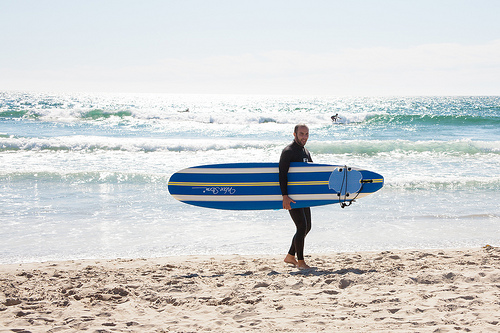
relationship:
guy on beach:
[278, 123, 320, 272] [0, 248, 484, 331]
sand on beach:
[0, 243, 500, 331] [0, 92, 499, 332]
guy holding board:
[278, 123, 320, 272] [165, 162, 384, 209]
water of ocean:
[23, 100, 130, 257] [73, 32, 490, 326]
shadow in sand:
[290, 267, 366, 276] [363, 258, 440, 285]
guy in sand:
[278, 123, 320, 272] [0, 243, 500, 331]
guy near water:
[278, 123, 320, 272] [3, 88, 498, 199]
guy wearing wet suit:
[278, 123, 320, 272] [278, 141, 313, 261]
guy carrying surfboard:
[270, 112, 323, 274] [155, 149, 391, 215]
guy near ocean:
[278, 123, 320, 272] [1, 99, 498, 173]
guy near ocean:
[278, 123, 320, 272] [0, 94, 498, 247]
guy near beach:
[278, 123, 320, 272] [6, 228, 498, 331]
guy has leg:
[278, 123, 320, 272] [285, 211, 303, 265]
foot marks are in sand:
[124, 262, 197, 286] [0, 243, 500, 331]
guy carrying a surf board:
[278, 123, 320, 272] [165, 158, 385, 212]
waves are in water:
[132, 67, 370, 162] [38, 83, 468, 295]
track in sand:
[248, 274, 275, 294] [0, 243, 500, 331]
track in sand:
[0, 251, 500, 333] [0, 243, 500, 331]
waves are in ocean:
[0, 95, 500, 215] [29, 63, 489, 240]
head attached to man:
[268, 119, 329, 149] [247, 114, 399, 296]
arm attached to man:
[280, 145, 295, 210] [278, 124, 311, 268]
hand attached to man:
[277, 195, 297, 212] [272, 120, 317, 272]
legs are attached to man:
[284, 203, 314, 271] [282, 123, 315, 270]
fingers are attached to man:
[281, 194, 296, 212] [188, 107, 418, 327]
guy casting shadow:
[278, 123, 320, 272] [288, 262, 378, 282]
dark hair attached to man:
[294, 123, 310, 135] [277, 124, 318, 271]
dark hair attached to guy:
[294, 125, 304, 135] [278, 123, 320, 272]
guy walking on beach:
[278, 123, 320, 272] [14, 75, 497, 320]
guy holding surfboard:
[278, 123, 320, 272] [162, 158, 387, 213]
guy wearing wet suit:
[278, 123, 320, 272] [287, 204, 309, 231]